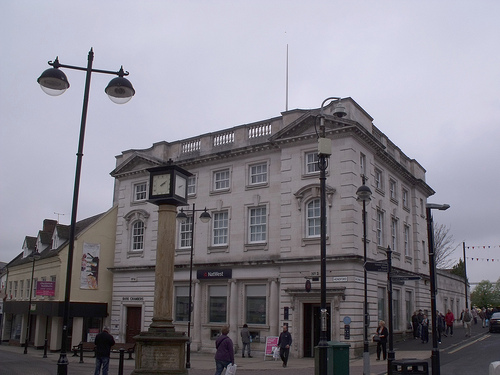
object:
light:
[37, 67, 70, 98]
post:
[56, 48, 95, 374]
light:
[103, 76, 136, 105]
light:
[176, 212, 189, 223]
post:
[184, 204, 196, 368]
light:
[198, 212, 212, 223]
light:
[333, 102, 348, 118]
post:
[313, 97, 340, 374]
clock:
[145, 166, 193, 206]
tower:
[130, 206, 193, 374]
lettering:
[144, 345, 179, 367]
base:
[131, 331, 192, 373]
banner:
[78, 241, 103, 289]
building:
[1, 203, 117, 356]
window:
[129, 216, 146, 253]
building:
[106, 96, 435, 360]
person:
[241, 323, 254, 361]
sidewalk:
[0, 315, 498, 374]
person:
[278, 323, 293, 368]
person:
[374, 321, 389, 363]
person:
[462, 307, 475, 340]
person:
[445, 309, 456, 337]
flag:
[468, 246, 470, 249]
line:
[464, 243, 499, 250]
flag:
[472, 246, 474, 249]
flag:
[477, 245, 479, 248]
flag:
[488, 245, 490, 248]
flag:
[494, 245, 496, 248]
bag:
[373, 333, 383, 342]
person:
[215, 326, 239, 374]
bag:
[226, 363, 238, 375]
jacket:
[212, 334, 237, 367]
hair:
[221, 325, 231, 336]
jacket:
[276, 330, 293, 347]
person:
[94, 326, 116, 374]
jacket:
[93, 331, 116, 358]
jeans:
[215, 359, 231, 374]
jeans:
[96, 354, 109, 374]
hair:
[102, 326, 110, 333]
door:
[316, 305, 330, 357]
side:
[352, 97, 440, 360]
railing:
[168, 115, 282, 163]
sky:
[0, 1, 500, 306]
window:
[174, 283, 192, 320]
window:
[208, 286, 228, 323]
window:
[244, 282, 267, 325]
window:
[378, 286, 387, 323]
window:
[392, 288, 401, 329]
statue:
[129, 156, 194, 374]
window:
[305, 196, 329, 239]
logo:
[197, 267, 234, 280]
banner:
[36, 280, 56, 297]